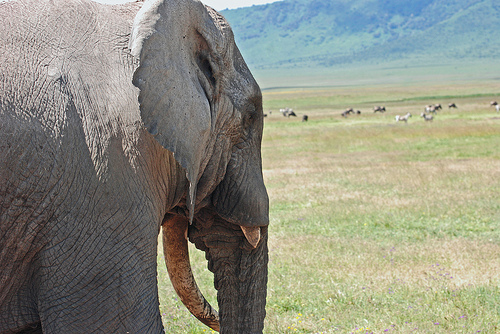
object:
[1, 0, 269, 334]
elephant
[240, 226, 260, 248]
tusk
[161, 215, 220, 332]
tusk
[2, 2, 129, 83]
light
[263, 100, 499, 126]
animals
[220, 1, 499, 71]
hill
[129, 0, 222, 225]
ear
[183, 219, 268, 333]
trunk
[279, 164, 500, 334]
grass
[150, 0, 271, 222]
head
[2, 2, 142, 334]
body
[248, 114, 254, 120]
eye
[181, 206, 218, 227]
mouth